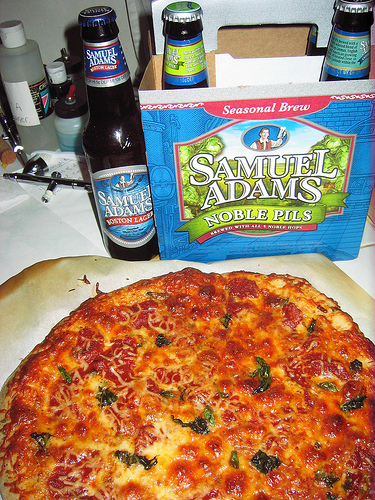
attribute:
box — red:
[131, 49, 365, 251]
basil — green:
[183, 399, 222, 438]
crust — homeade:
[0, 299, 68, 401]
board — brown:
[28, 257, 365, 360]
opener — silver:
[11, 134, 106, 221]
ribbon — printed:
[179, 200, 327, 239]